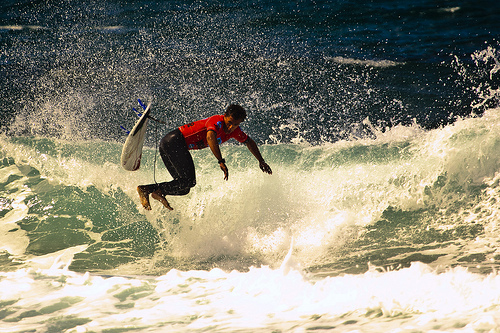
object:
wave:
[8, 126, 498, 261]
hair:
[222, 103, 248, 122]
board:
[121, 94, 155, 171]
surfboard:
[115, 94, 163, 175]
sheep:
[340, 48, 468, 217]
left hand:
[256, 159, 274, 176]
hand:
[214, 160, 230, 181]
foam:
[253, 99, 451, 258]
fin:
[123, 93, 165, 132]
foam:
[104, 223, 498, 331]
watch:
[210, 154, 227, 168]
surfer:
[109, 77, 278, 217]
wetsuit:
[143, 129, 202, 199]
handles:
[131, 95, 142, 124]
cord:
[144, 111, 159, 187]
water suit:
[138, 113, 248, 197]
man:
[135, 101, 272, 214]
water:
[0, 3, 499, 329]